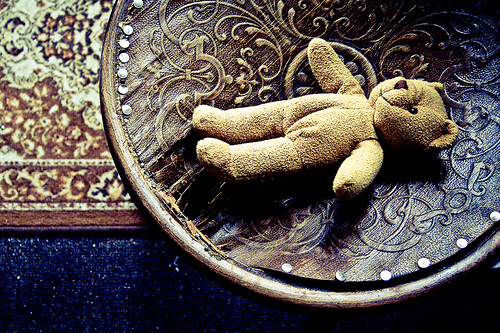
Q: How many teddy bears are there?
A: One.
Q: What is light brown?
A: Teddy bear.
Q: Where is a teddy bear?
A: In a large bowl.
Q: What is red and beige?
A: A rug.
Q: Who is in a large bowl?
A: Stuffed animal.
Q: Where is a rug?
A: On the floor.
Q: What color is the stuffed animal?
A: Light brown.